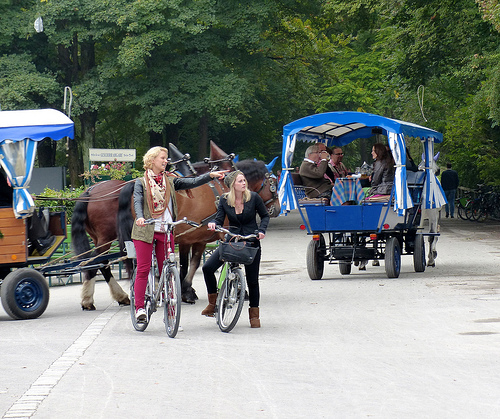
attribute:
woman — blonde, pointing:
[222, 174, 265, 249]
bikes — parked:
[142, 247, 241, 318]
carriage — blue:
[301, 208, 377, 231]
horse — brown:
[181, 199, 185, 201]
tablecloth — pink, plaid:
[341, 193, 342, 194]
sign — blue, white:
[91, 147, 132, 165]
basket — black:
[211, 238, 254, 264]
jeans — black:
[244, 256, 261, 300]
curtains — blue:
[272, 109, 298, 217]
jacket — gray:
[130, 198, 151, 208]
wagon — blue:
[383, 198, 434, 233]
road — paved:
[263, 307, 389, 358]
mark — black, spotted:
[467, 291, 485, 299]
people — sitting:
[284, 143, 396, 196]